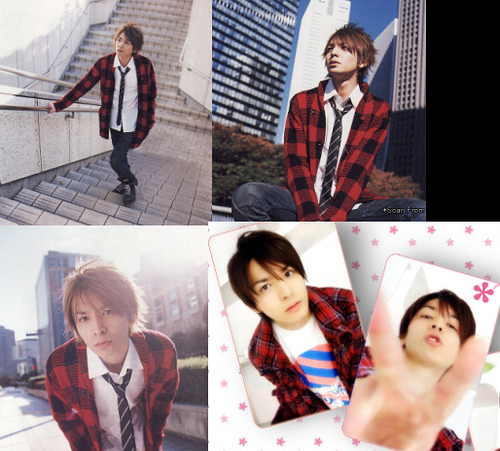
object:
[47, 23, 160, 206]
person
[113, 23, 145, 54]
hair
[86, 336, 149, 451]
shirt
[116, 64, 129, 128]
tie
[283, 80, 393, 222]
shirt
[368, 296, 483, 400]
peace sign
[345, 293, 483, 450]
fingers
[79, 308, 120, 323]
eyebrows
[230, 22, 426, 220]
man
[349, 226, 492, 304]
stars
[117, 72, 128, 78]
knot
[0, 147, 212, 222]
stairs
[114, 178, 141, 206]
shoes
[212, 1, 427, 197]
buildings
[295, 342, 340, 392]
design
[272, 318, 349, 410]
shirt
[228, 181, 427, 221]
jeans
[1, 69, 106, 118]
rail